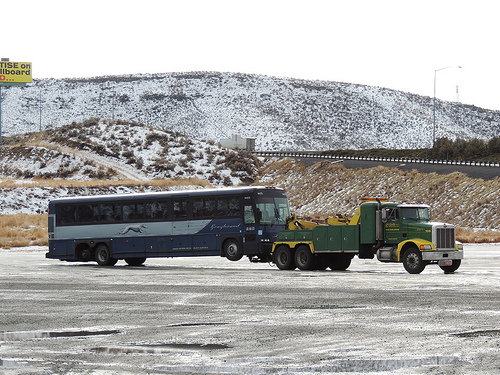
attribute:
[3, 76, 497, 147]
snow — white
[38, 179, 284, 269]
bus — greyhouse 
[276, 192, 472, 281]
tow truck — green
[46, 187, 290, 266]
bus — blue, broken, grey and blue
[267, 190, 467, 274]
truck — heavy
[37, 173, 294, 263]
bus — blue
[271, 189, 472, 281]
truck — green and yellow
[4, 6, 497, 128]
sky — blue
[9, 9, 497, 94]
sky — blue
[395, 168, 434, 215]
ground — snowy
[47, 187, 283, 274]
bus — blue and silver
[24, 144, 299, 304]
bus — blue and silver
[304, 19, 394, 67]
clouds — white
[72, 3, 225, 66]
sky — blue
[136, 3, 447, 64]
sky — blue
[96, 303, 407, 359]
ground — frozen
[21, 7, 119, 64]
clouds — white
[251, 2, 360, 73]
clouds — white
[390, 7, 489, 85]
clouds — white